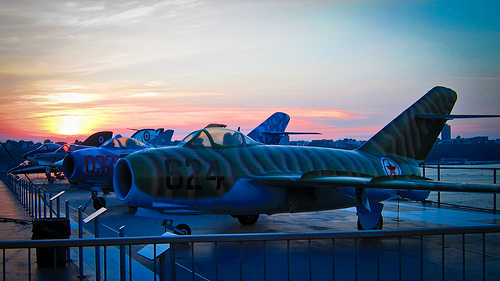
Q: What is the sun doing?
A: Setting.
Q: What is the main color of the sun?
A: Yellow.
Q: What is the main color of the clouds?
A: Gray.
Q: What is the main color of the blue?
A: Blue.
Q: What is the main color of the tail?
A: Green.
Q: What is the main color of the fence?
A: Green.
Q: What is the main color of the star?
A: Black.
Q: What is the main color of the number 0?
A: Black.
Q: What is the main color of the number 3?
A: Black.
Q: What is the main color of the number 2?
A: Black.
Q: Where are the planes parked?
A: On concrete.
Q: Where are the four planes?
A: Airport.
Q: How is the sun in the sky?
A: Setting.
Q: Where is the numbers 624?
A: On plane.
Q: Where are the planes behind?
A: A fence.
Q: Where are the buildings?
A: In back.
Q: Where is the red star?
A: On plane.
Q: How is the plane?
A: Parked.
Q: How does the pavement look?
A: Wet.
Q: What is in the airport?
A: There are airplanes in the airport.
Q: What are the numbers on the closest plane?
A: 624.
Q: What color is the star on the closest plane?
A: Red.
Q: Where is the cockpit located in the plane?
A: Top.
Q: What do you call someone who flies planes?
A: Pilot.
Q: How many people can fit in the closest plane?
A: One.